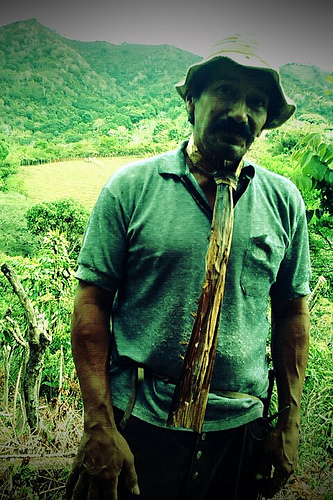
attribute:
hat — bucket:
[145, 43, 289, 120]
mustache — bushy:
[210, 118, 254, 145]